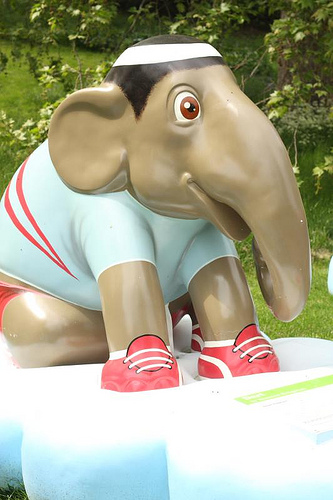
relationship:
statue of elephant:
[1, 35, 332, 499] [0, 34, 312, 392]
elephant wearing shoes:
[0, 34, 312, 392] [101, 322, 280, 392]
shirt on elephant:
[1, 138, 241, 312] [0, 34, 312, 392]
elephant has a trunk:
[0, 34, 312, 392] [193, 85, 311, 323]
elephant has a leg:
[0, 34, 312, 392] [80, 207, 183, 393]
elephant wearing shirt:
[0, 34, 312, 392] [1, 138, 241, 312]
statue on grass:
[1, 35, 332, 499] [1, 12, 333, 340]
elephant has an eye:
[0, 34, 312, 392] [179, 95, 200, 121]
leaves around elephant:
[1, 0, 332, 194] [0, 34, 312, 392]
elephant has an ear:
[0, 34, 312, 392] [47, 83, 127, 196]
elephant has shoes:
[0, 34, 312, 392] [101, 322, 280, 392]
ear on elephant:
[47, 83, 127, 196] [0, 34, 312, 392]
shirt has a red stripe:
[1, 138, 241, 312] [3, 157, 81, 284]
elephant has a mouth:
[0, 34, 312, 392] [186, 174, 251, 241]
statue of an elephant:
[1, 35, 332, 499] [0, 34, 312, 392]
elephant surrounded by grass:
[0, 34, 312, 392] [1, 12, 333, 340]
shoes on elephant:
[101, 322, 280, 392] [0, 34, 312, 392]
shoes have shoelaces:
[101, 322, 280, 392] [121, 337, 273, 372]